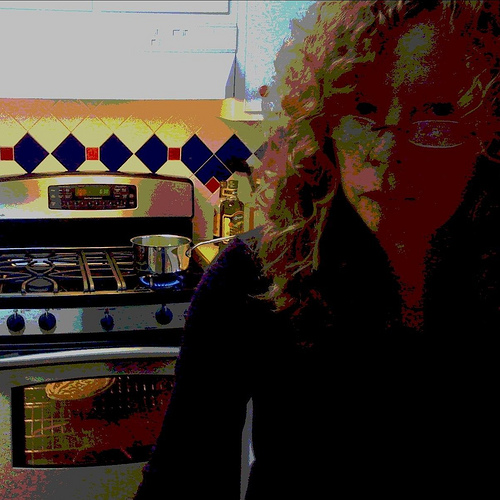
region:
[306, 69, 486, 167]
glasses on girl's face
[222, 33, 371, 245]
hair on the lady's head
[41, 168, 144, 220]
oven with lights on it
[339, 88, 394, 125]
eye of the lady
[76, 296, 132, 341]
knob on the oven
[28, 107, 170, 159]
wall behind the oven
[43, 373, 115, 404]
pie baking in the oven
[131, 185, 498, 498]
black long sleeved shirt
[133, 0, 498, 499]
woman with wavy blonde hair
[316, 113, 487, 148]
rimless eyeglasses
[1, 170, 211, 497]
stainless steel oven and stove top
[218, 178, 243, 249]
bottle of olive oil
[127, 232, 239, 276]
stainless steel pot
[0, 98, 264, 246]
white, red and blue back splash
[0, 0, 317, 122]
white cabinets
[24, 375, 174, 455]
silver metal oven racks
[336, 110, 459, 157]
women wearing glasses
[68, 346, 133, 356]
handle on the oven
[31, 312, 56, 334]
knobs on the stove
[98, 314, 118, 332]
a knob that is black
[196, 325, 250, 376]
a long sleeve shirt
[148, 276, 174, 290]
fire is blue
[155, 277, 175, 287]
fire on the stove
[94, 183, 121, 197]
the time on the stove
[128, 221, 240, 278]
a metal pot on the stove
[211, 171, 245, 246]
a small bottle of sauce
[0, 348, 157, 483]
oven door with glass pane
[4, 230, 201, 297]
a gas burner stove top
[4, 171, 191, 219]
the control panel of an oven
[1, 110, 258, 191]
a wall with a pattern in its tiles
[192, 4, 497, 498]
a woman with glasses and curly hair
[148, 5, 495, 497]
blonde haired woman in a kitchen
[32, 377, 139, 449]
a pizza cooking in an oven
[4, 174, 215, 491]
an oven with food inside of it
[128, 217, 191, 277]
a pot on the stove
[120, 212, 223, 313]
a pot on the stove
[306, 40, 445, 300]
woman is wearing eyeglasses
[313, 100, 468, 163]
a pair of glasses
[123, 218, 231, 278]
a silver cooking pan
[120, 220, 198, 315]
a pan on the stove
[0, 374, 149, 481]
the oven light is on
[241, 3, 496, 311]
a woman in the background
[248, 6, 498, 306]
a woman wearing glasses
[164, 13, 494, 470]
a woman wearing a black top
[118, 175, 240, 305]
a pot on the stove